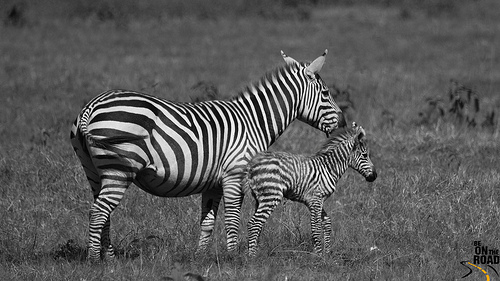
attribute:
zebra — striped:
[234, 122, 379, 263]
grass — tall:
[4, 25, 83, 270]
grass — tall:
[20, 13, 497, 53]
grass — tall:
[128, 194, 497, 278]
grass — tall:
[365, 111, 495, 276]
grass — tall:
[336, 17, 498, 207]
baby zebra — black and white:
[236, 118, 378, 262]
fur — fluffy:
[318, 124, 359, 161]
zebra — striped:
[240, 123, 375, 257]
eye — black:
[317, 86, 335, 98]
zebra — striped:
[67, 42, 349, 272]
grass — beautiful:
[3, 0, 499, 280]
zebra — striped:
[53, 49, 391, 264]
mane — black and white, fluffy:
[320, 128, 354, 154]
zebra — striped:
[58, 31, 420, 251]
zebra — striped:
[64, 46, 340, 250]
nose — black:
[366, 167, 381, 182]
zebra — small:
[241, 107, 396, 257]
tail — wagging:
[79, 102, 153, 147]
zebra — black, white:
[62, 22, 402, 267]